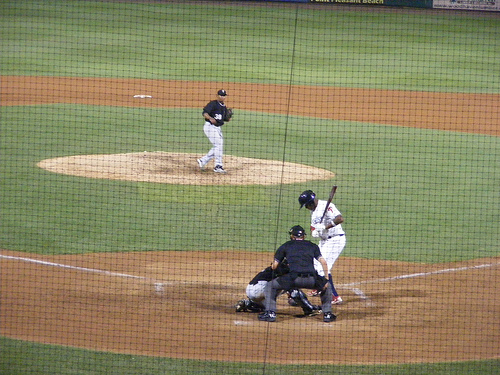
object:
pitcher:
[196, 89, 234, 174]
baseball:
[0, 4, 493, 365]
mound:
[36, 151, 334, 185]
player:
[298, 189, 347, 304]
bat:
[319, 185, 338, 224]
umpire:
[257, 225, 336, 324]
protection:
[256, 225, 336, 323]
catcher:
[249, 265, 282, 285]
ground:
[50, 173, 168, 286]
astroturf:
[39, 10, 374, 78]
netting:
[1, 4, 68, 360]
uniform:
[311, 199, 346, 276]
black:
[203, 100, 231, 127]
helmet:
[298, 190, 315, 210]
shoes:
[331, 296, 343, 304]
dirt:
[165, 265, 232, 352]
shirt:
[274, 240, 322, 272]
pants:
[264, 277, 332, 313]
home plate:
[280, 308, 300, 319]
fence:
[391, 0, 498, 10]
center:
[5, 89, 470, 205]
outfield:
[4, 1, 486, 75]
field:
[1, 3, 500, 142]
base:
[117, 109, 158, 114]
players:
[195, 89, 233, 174]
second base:
[133, 94, 152, 99]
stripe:
[327, 206, 333, 213]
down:
[265, 246, 278, 258]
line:
[338, 287, 377, 306]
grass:
[180, 194, 287, 246]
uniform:
[200, 100, 232, 168]